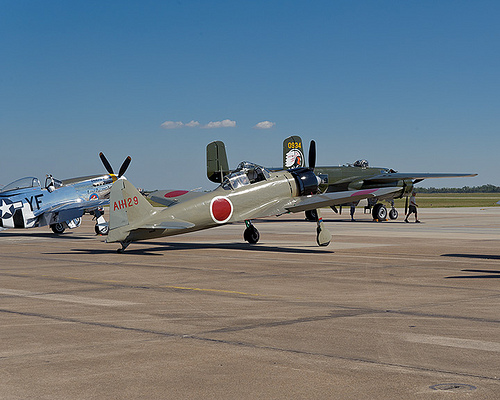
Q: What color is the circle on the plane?
A: Red.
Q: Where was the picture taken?
A: At the airport.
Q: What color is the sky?
A: Blue.